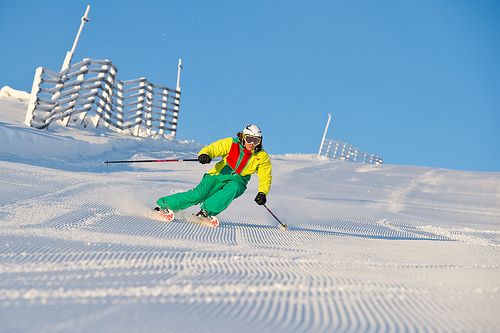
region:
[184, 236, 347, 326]
vertical ski lines on the snow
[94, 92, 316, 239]
person skiing down a slope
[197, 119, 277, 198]
yellow, red, green, snow jacket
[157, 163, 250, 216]
bright green ski pants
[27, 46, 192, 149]
white wooden fence near snow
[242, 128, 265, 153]
face with ski goggles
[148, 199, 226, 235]
red and white skiis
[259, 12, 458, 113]
beautiful blue clear sky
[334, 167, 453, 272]
down hill smooth snow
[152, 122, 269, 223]
a downhill skier on the ski slope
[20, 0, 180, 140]
ski trail markers and fence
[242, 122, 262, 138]
the skier is wearing a ski helmet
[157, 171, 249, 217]
the skier is wearing green ski pants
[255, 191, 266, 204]
the skier is wearing black ski gloves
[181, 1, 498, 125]
the sky is blue without any clouds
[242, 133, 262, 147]
the skier is wearing yellow ski goggles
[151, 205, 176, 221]
the skis are white and red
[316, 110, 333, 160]
ski depth marking pole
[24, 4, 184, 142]
gate marking a no skiing area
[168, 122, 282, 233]
skier skiing down mountain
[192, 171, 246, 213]
skier wearing green pants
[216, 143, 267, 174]
skier wearing green yellow and red jacket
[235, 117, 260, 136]
skier wearing white helmet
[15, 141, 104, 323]
white snow on mountain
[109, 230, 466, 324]
white snow on mountain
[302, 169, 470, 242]
white snow on mountain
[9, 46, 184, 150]
white fence on snowy mountain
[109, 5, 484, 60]
blue sky without clouds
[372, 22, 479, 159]
blue sky without clouds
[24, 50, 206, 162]
a fence in the snow.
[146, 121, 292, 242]
a man in a colorful outfit.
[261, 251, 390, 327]
tracks in the snow.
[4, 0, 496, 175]
a clear blue sky.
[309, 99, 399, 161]
a fence standing in the snow.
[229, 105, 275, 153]
a helmet on a person's head.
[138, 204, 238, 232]
a pair of skis in the snow.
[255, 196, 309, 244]
a ski pole in a person's hand.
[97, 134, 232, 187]
a left hand ski pole.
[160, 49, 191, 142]
a tall piece of wood.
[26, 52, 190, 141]
snow caked fence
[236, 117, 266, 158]
person with a white helmet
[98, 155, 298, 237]
two long, black ski poles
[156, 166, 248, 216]
green snowpants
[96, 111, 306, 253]
brightly dressed skier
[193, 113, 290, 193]
skier in a yellow jacket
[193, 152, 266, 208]
warm, black gloves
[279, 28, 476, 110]
bright, blue sky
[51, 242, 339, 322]
wavy grooves left by the snow groomer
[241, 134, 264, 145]
yellow and white goggles